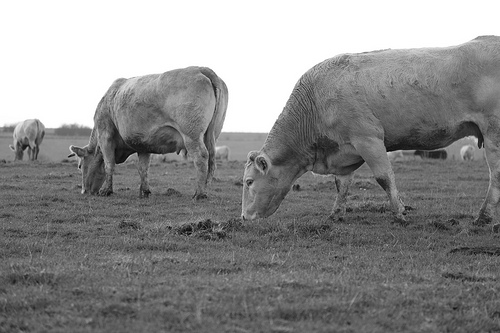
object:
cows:
[384, 149, 403, 160]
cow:
[65, 65, 230, 202]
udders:
[475, 131, 485, 149]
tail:
[202, 69, 224, 175]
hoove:
[94, 182, 115, 196]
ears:
[68, 144, 87, 159]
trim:
[218, 140, 275, 250]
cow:
[238, 34, 500, 235]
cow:
[7, 117, 48, 163]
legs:
[348, 135, 410, 228]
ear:
[252, 150, 272, 175]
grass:
[100, 246, 179, 294]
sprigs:
[47, 231, 82, 268]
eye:
[243, 175, 258, 187]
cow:
[410, 148, 448, 162]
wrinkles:
[290, 101, 314, 140]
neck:
[262, 93, 321, 174]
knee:
[332, 178, 348, 193]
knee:
[373, 173, 395, 189]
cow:
[458, 143, 476, 164]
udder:
[173, 137, 185, 156]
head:
[64, 143, 107, 196]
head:
[238, 149, 294, 221]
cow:
[215, 145, 230, 161]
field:
[0, 123, 499, 332]